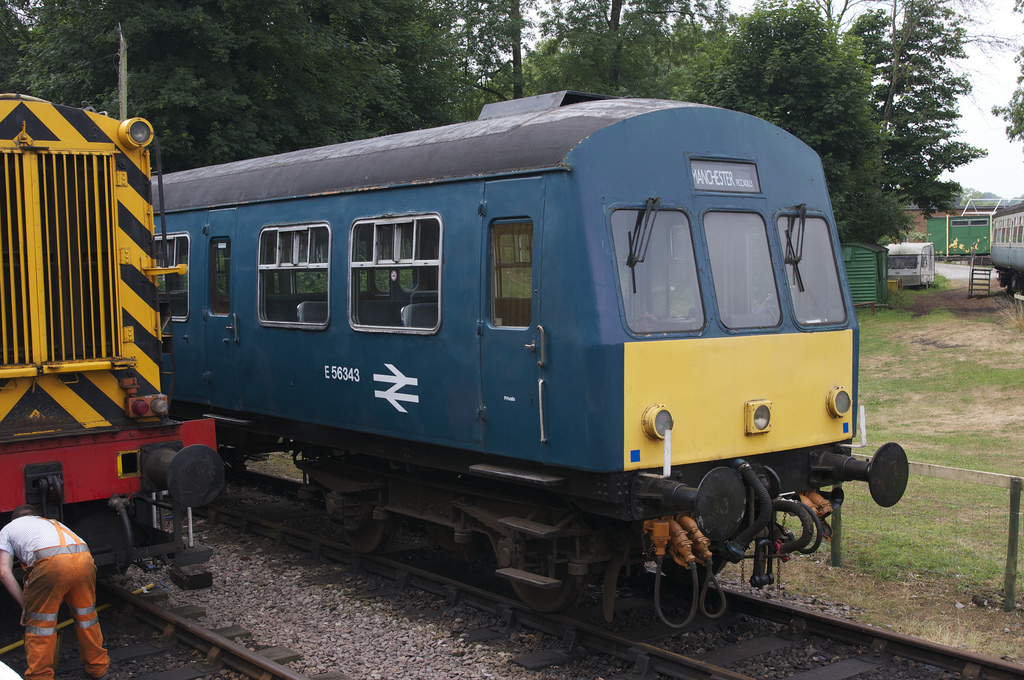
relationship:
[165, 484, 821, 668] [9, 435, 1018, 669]
metal rail on train track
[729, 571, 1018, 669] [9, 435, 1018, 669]
metal rail on train track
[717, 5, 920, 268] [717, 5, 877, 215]
tree has leaves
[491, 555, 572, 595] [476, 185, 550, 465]
step under door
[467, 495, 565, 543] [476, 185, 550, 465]
step under door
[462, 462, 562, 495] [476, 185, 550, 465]
step under door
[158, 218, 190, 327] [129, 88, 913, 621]
window on side of train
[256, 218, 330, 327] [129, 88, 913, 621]
window on side of train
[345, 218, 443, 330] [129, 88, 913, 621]
window on side of train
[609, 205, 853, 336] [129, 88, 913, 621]
windshield on train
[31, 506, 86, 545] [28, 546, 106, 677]
suspenders holding pants